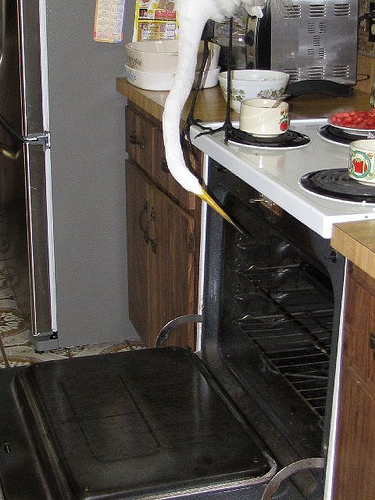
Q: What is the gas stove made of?
A: Metal.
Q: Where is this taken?
A: A kitchen.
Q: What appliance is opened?
A: The oven.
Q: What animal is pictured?
A: A white bird, maybe an egret.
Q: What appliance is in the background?
A: A refrigerator.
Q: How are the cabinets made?
A: From dark wood.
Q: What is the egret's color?
A: White.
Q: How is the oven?
A: Empty.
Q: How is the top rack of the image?
A: Oven.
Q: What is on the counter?
A: Oven.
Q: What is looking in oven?
A: White bird.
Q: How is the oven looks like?
A: Open.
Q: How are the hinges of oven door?
A: Silver.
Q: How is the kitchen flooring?
A: Patterned.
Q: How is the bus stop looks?
A: Burners.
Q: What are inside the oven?
A: Two racks.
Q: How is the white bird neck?
A: Long.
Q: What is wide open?
A: Oven door.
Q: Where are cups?
A: On stove burners.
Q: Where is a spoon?
A: In a cup.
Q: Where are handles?
A: On cabinets.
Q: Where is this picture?
A: Kitchen.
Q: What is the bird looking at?
A: Oven.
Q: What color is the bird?
A: White.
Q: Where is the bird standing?
A: Counter.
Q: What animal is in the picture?
A: Bird.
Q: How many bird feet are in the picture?
A: Two.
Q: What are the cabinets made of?
A: Wood.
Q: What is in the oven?
A: Nothing.